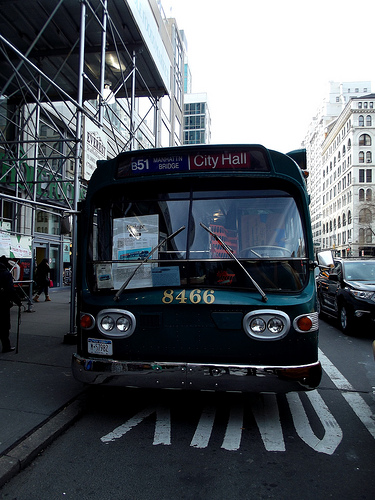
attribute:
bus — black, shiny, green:
[69, 145, 322, 394]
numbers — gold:
[160, 284, 216, 305]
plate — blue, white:
[87, 336, 114, 357]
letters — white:
[101, 387, 343, 454]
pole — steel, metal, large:
[68, 0, 87, 344]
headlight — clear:
[268, 320, 285, 335]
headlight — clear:
[250, 319, 267, 337]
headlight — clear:
[117, 316, 129, 333]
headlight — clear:
[100, 316, 114, 333]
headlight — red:
[296, 316, 313, 333]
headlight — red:
[76, 311, 97, 335]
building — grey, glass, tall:
[299, 81, 373, 265]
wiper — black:
[193, 218, 270, 307]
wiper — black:
[114, 223, 188, 301]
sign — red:
[189, 149, 250, 169]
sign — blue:
[127, 151, 190, 175]